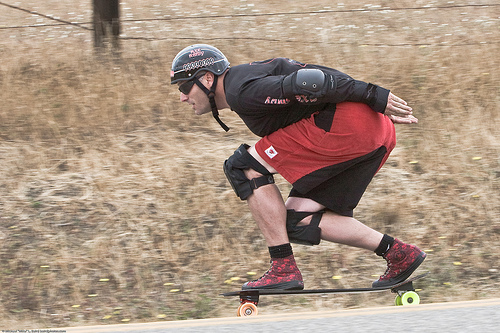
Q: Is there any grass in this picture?
A: Yes, there is grass.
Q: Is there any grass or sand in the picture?
A: Yes, there is grass.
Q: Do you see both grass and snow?
A: No, there is grass but no snow.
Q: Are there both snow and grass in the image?
A: No, there is grass but no snow.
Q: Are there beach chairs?
A: No, there are no beach chairs.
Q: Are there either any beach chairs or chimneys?
A: No, there are no beach chairs or chimneys.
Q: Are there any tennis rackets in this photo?
A: No, there are no tennis rackets.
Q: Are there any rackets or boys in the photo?
A: No, there are no rackets or boys.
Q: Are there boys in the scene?
A: No, there are no boys.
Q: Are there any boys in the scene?
A: No, there are no boys.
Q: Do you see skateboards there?
A: Yes, there is a skateboard.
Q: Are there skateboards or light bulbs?
A: Yes, there is a skateboard.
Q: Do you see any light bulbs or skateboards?
A: Yes, there is a skateboard.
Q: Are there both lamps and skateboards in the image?
A: No, there is a skateboard but no lamps.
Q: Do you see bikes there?
A: No, there are no bikes.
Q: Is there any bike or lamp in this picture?
A: No, there are no bikes or lamps.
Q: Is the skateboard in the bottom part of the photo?
A: Yes, the skateboard is in the bottom of the image.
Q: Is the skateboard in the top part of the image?
A: No, the skateboard is in the bottom of the image.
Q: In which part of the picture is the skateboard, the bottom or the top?
A: The skateboard is in the bottom of the image.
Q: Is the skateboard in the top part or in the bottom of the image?
A: The skateboard is in the bottom of the image.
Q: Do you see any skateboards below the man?
A: Yes, there is a skateboard below the man.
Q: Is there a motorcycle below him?
A: No, there is a skateboard below the man.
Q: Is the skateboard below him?
A: Yes, the skateboard is below the man.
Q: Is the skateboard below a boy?
A: No, the skateboard is below the man.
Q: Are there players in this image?
A: No, there are no players.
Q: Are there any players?
A: No, there are no players.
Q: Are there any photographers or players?
A: No, there are no players or photographers.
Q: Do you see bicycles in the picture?
A: No, there are no bicycles.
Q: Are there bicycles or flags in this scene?
A: No, there are no bicycles or flags.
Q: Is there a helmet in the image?
A: Yes, there is a helmet.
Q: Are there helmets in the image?
A: Yes, there is a helmet.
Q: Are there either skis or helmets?
A: Yes, there is a helmet.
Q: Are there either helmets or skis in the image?
A: Yes, there is a helmet.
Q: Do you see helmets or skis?
A: Yes, there is a helmet.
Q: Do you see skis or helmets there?
A: Yes, there is a helmet.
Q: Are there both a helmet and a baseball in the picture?
A: No, there is a helmet but no baseballs.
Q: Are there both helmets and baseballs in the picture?
A: No, there is a helmet but no baseballs.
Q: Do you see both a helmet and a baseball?
A: No, there is a helmet but no baseballs.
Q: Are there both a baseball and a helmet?
A: No, there is a helmet but no baseballs.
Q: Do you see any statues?
A: No, there are no statues.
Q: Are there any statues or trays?
A: No, there are no statues or trays.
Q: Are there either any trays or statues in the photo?
A: No, there are no statues or trays.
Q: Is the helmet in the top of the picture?
A: Yes, the helmet is in the top of the image.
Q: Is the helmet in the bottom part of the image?
A: No, the helmet is in the top of the image.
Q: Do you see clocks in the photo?
A: No, there are no clocks.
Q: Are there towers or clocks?
A: No, there are no clocks or towers.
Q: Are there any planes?
A: No, there are no planes.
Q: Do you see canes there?
A: No, there are no canes.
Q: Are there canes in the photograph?
A: No, there are no canes.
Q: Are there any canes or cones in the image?
A: No, there are no canes or cones.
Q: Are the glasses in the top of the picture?
A: Yes, the glasses are in the top of the image.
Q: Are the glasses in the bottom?
A: No, the glasses are in the top of the image.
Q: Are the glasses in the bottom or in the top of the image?
A: The glasses are in the top of the image.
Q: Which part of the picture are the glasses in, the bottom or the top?
A: The glasses are in the top of the image.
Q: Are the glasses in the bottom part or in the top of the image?
A: The glasses are in the top of the image.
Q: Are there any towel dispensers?
A: No, there are no towel dispensers.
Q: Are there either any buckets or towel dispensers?
A: No, there are no towel dispensers or buckets.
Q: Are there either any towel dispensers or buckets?
A: No, there are no towel dispensers or buckets.